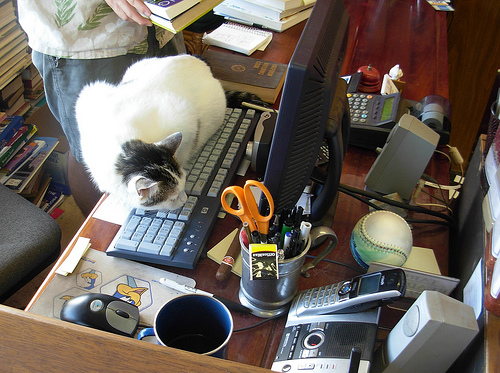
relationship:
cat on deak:
[75, 53, 228, 212] [24, 0, 497, 372]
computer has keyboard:
[257, 0, 352, 226] [106, 106, 278, 270]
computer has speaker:
[257, 0, 352, 226] [366, 113, 440, 199]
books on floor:
[1, 111, 65, 216] [2, 192, 90, 311]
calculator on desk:
[346, 92, 454, 148] [25, 0, 451, 370]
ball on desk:
[350, 210, 413, 272] [25, 0, 451, 370]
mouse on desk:
[60, 293, 142, 337] [25, 0, 451, 370]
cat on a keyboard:
[75, 53, 228, 212] [106, 106, 278, 270]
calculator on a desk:
[346, 92, 454, 148] [25, 0, 451, 370]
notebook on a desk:
[200, 21, 275, 56] [25, 0, 451, 370]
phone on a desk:
[270, 268, 407, 372] [25, 0, 451, 370]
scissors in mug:
[219, 179, 277, 243] [240, 224, 340, 317]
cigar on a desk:
[216, 220, 244, 282] [25, 0, 451, 370]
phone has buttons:
[270, 268, 407, 372] [304, 281, 351, 312]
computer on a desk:
[257, 0, 352, 226] [25, 0, 451, 370]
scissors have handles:
[219, 179, 277, 243] [221, 178, 276, 233]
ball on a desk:
[350, 210, 413, 272] [25, 0, 451, 370]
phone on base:
[270, 268, 407, 372] [273, 300, 380, 370]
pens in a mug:
[242, 206, 311, 256] [240, 224, 340, 317]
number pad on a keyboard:
[115, 214, 185, 256] [106, 106, 278, 270]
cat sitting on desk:
[75, 53, 228, 212] [25, 0, 451, 370]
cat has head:
[75, 53, 228, 212] [123, 131, 189, 213]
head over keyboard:
[123, 131, 189, 213] [106, 106, 278, 270]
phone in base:
[270, 268, 407, 372] [273, 300, 380, 370]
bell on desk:
[356, 64, 383, 91] [25, 0, 451, 370]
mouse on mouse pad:
[60, 293, 142, 337] [28, 244, 198, 344]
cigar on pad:
[216, 220, 244, 282] [207, 224, 246, 276]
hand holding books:
[106, 1, 152, 28] [142, 1, 228, 35]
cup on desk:
[138, 293, 235, 360] [25, 0, 451, 370]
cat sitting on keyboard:
[75, 53, 228, 212] [106, 106, 278, 270]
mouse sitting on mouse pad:
[60, 293, 142, 337] [28, 244, 198, 344]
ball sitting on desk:
[350, 210, 413, 272] [25, 0, 451, 370]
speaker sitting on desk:
[366, 113, 440, 199] [25, 0, 451, 370]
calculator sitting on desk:
[346, 92, 454, 148] [25, 0, 451, 370]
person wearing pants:
[18, 2, 152, 214] [32, 49, 147, 161]